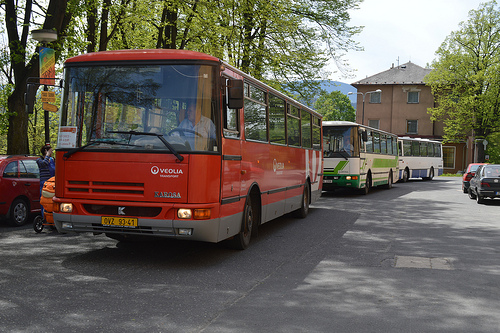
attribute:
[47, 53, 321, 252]
bus — red, orange 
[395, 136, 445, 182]
bus — white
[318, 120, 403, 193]
bus — green , white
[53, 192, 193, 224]
lights — bus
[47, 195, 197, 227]
lights — bus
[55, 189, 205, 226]
lights — bus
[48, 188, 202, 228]
lights — bus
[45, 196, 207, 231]
lights — bus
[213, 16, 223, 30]
tree — green leaves 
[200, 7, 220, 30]
tree — green leaves 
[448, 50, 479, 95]
tree — green leaves 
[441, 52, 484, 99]
tree — green leaves 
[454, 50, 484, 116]
tree — green leaves 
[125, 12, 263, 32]
tree — green leaves 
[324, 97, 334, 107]
tree — green leaves 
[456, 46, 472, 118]
tree — green leaves 